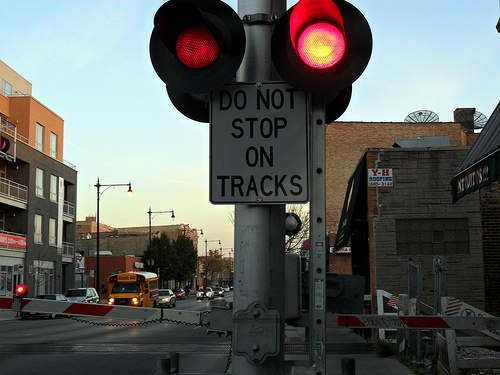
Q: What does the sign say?
A: Do not stop on tracks.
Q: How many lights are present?
A: Two lights.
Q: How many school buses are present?
A: One.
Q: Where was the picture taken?
A: At the side of the street.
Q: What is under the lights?
A: The sign.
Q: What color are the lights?
A: Red.